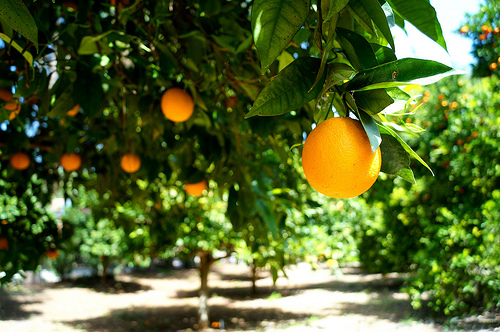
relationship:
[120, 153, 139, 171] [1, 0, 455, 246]
orange hanging on tree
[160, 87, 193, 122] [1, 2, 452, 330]
orange hanging on tree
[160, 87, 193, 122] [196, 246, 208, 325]
orange hanging on tree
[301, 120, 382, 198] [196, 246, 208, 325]
orange hanging on tree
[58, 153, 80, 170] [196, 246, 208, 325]
orange hanging on tree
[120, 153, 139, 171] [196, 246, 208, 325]
orange hanging on tree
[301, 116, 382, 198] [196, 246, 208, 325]
orange hanging on tree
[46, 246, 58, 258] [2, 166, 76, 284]
orange hanging on tree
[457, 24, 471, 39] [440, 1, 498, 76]
orange hanging on tree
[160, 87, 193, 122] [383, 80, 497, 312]
orange in tree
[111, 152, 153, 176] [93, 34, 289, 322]
orange in tree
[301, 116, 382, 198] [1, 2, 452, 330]
orange in tree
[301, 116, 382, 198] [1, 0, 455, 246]
orange in tree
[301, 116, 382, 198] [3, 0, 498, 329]
orange in tree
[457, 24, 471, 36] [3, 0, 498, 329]
orange in tree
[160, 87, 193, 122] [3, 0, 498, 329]
orange in tree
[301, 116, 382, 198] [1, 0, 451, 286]
orange in trees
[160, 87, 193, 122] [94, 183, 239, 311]
orange in trees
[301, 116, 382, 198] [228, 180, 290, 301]
orange in trees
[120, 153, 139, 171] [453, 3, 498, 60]
orange in trees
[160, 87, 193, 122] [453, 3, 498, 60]
orange in trees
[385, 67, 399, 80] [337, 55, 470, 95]
bug hole in leaf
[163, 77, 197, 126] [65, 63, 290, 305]
orange hanging on a tree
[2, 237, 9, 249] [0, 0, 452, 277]
orange hanging on a tree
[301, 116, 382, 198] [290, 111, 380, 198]
orange in tree